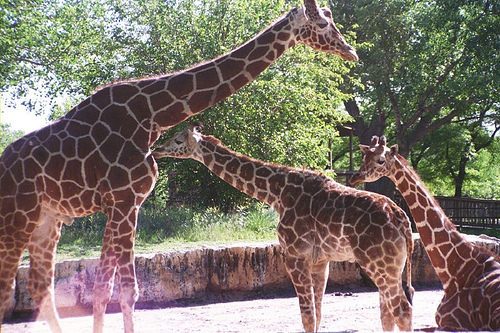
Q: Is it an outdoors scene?
A: Yes, it is outdoors.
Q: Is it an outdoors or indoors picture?
A: It is outdoors.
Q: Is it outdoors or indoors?
A: It is outdoors.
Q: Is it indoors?
A: No, it is outdoors.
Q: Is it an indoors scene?
A: No, it is outdoors.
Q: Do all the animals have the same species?
A: Yes, all the animals are giraffes.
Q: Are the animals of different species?
A: No, all the animals are giraffes.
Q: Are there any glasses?
A: No, there are no glasses.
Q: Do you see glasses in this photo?
A: No, there are no glasses.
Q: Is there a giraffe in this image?
A: Yes, there are giraffes.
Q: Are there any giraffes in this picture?
A: Yes, there are giraffes.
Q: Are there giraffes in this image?
A: Yes, there are giraffes.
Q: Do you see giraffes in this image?
A: Yes, there are giraffes.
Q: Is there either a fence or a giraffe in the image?
A: Yes, there are giraffes.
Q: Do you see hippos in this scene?
A: No, there are no hippos.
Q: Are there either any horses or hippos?
A: No, there are no hippos or horses.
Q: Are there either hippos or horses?
A: No, there are no hippos or horses.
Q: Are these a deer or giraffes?
A: These are giraffes.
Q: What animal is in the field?
A: The giraffes are in the field.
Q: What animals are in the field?
A: The animals are giraffes.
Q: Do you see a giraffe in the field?
A: Yes, there are giraffes in the field.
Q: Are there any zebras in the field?
A: No, there are giraffes in the field.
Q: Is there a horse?
A: No, there are no horses.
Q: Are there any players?
A: No, there are no players.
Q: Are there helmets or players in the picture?
A: No, there are no players or helmets.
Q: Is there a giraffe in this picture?
A: Yes, there is a giraffe.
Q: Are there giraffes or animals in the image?
A: Yes, there is a giraffe.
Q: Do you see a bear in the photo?
A: No, there are no bears.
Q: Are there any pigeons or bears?
A: No, there are no bears or pigeons.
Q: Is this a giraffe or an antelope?
A: This is a giraffe.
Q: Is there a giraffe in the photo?
A: Yes, there are giraffes.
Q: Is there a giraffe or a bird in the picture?
A: Yes, there are giraffes.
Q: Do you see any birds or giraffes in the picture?
A: Yes, there are giraffes.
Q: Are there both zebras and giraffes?
A: No, there are giraffes but no zebras.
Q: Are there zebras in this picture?
A: No, there are no zebras.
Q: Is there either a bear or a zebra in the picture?
A: No, there are no zebras or bears.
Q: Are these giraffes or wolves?
A: These are giraffes.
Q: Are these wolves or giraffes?
A: These are giraffes.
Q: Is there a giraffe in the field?
A: Yes, there are giraffes in the field.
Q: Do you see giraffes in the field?
A: Yes, there are giraffes in the field.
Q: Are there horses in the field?
A: No, there are giraffes in the field.